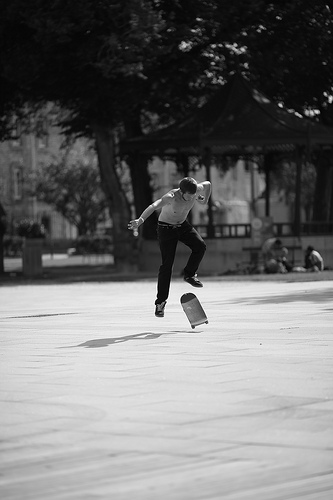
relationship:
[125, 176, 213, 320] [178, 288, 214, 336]
guy on board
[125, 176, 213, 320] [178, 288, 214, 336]
guy riding board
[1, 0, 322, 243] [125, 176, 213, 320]
trees behind guy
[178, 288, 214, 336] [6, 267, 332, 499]
board on ground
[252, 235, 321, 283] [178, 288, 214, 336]
guys sitting board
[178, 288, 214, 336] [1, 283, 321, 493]
board above ground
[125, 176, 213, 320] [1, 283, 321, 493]
guy above ground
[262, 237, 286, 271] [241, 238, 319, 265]
people huddled over bench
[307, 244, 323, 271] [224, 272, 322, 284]
guys crouched down on ground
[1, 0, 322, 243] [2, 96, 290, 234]
trees and building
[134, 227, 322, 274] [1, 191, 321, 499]
wall at edge of park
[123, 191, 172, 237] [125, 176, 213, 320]
arm forming slant guy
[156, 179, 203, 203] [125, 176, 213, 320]
shoulder forming slant guy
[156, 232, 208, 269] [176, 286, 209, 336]
knee over skateboard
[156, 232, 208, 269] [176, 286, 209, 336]
knee bent over skateboard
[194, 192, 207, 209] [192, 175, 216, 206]
hand curled under arm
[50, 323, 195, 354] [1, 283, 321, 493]
shadow on ground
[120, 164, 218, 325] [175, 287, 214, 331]
guy with skateboard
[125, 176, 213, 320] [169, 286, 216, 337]
guy playing skateboard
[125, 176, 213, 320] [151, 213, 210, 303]
guy wearing pants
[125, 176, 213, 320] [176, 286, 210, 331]
guy playing skateboard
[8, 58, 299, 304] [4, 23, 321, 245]
building in background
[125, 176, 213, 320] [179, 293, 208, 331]
guy playing board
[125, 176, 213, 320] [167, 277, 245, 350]
guy playing skateboard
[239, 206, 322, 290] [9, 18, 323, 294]
people in background